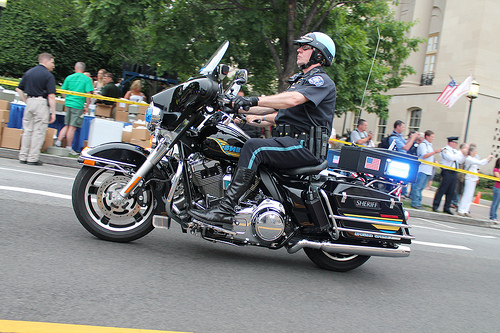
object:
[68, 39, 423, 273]
motorcycle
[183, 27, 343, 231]
officer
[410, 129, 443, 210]
person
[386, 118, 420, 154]
person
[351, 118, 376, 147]
person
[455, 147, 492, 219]
person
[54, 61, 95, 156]
person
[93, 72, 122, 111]
person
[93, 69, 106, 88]
person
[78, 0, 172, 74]
tree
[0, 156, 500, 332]
street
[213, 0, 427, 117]
tree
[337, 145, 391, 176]
garbage can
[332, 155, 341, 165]
american flag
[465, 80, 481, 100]
street light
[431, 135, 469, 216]
person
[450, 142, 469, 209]
person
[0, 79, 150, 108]
tape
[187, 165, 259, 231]
boot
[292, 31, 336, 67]
helmet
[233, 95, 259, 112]
glove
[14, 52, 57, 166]
man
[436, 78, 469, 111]
american flag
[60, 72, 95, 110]
shirt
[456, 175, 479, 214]
pants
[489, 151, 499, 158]
camera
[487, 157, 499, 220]
person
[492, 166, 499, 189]
top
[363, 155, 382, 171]
american flag decal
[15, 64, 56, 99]
shirt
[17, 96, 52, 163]
pants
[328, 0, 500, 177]
building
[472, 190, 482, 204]
cone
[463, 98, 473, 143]
post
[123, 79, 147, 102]
woman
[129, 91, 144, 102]
tank top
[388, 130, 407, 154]
shirt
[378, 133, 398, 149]
backpack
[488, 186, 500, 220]
jeans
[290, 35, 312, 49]
part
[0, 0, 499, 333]
picture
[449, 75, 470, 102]
pole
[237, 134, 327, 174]
pants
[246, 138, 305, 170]
strip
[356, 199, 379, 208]
word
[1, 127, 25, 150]
box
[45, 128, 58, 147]
box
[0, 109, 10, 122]
box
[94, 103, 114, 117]
box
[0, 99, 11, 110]
box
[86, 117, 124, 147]
box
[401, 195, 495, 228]
sidewalk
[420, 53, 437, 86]
window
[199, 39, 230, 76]
windshied